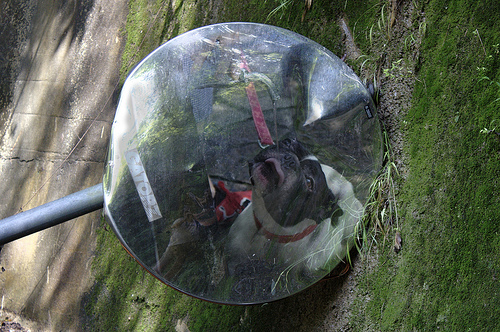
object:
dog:
[227, 135, 364, 278]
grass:
[269, 130, 399, 299]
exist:
[35, 23, 37, 31]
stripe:
[243, 80, 278, 150]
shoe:
[210, 180, 252, 225]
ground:
[0, 0, 499, 332]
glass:
[101, 22, 384, 308]